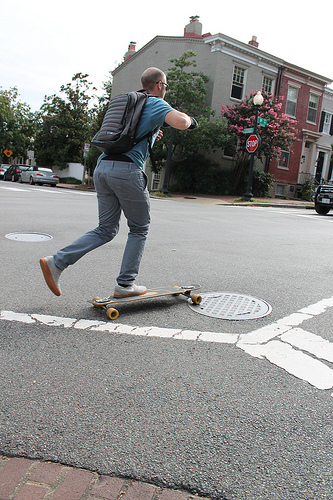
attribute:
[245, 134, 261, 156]
sign — red, stop sign, white, at intersection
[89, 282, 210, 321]
skate board — old style, in image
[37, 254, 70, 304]
shoe — white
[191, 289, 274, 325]
cover — metal, gray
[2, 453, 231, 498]
bricks — red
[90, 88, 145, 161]
back pack — grey, gray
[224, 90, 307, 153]
flowers — pink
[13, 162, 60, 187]
car — silver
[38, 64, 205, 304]
man — not in crosswalk, thin haired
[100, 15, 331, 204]
building — apartment building, gray, tall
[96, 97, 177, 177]
shirt — green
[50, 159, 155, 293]
pants — gray, blue, denim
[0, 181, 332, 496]
street — black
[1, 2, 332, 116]
sky — overcast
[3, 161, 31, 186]
car — black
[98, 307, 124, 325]
wheel — yellow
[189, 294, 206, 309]
wheel — yellow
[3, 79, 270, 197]
trees — green